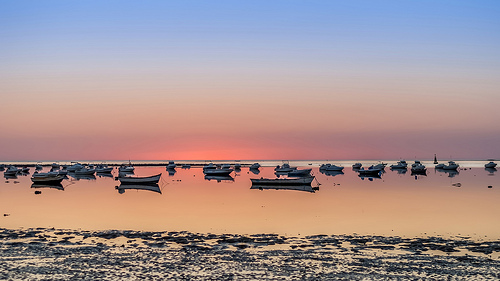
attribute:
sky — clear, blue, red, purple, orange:
[122, 15, 166, 47]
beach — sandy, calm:
[99, 198, 119, 211]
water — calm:
[237, 199, 267, 211]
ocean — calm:
[250, 205, 270, 215]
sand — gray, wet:
[106, 205, 131, 216]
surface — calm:
[80, 210, 105, 221]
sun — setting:
[196, 141, 288, 156]